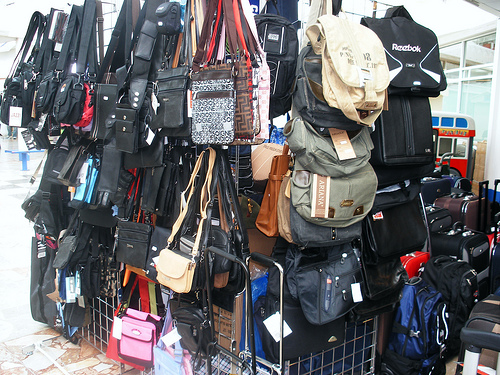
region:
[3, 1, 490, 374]
several bags on display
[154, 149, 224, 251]
long tan strap on the bag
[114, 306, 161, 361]
pink and purple bag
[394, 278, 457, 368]
black and blue backpack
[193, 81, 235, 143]
blue design on the purse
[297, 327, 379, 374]
section of the displat with no bags on it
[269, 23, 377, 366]
a row of messenger bags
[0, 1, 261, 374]
several purse on display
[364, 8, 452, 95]
black and white bag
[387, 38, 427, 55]
Reebok logo on the front of the bag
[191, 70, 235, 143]
purse with a letter pattern on it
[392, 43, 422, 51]
brand name on the bag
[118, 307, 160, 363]
pink and black purse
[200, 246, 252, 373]
black luggage cart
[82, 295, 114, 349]
wire display rack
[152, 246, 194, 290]
small tan purse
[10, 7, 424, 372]
display of bags and purses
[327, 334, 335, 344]
metal logo on the bag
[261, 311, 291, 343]
paper tag on the black bag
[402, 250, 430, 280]
a red suit case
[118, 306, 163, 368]
pink bag on display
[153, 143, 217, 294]
tan purse on display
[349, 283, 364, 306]
white tag on a bag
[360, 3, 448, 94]
black and white Reebok bag on display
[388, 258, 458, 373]
blue and black backpack on display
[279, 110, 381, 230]
olive colored bag on display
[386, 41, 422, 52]
white print on a bag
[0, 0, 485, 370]
many different bags on a rack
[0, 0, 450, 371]
many different bags on display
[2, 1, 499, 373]
many different bags on a silver rack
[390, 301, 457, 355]
Blue and black bag hanging on rack.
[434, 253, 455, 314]
Black bag hanging on rack.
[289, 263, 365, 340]
Black bag hanging on bag.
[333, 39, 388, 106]
Tan bag hanging on rack.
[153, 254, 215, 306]
Tan bag hanging on rack.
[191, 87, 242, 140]
Black bag hanging on rack.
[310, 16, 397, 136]
the bag is white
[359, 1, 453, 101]
the bag is black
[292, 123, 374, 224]
the bags are green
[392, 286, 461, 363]
bag is blue and black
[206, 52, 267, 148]
the bag is brown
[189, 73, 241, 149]
the bag is gray and white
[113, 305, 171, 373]
bag is pink and black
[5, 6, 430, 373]
bags are on a rack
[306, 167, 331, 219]
brown stripe on bag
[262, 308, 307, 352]
white tag on the bag